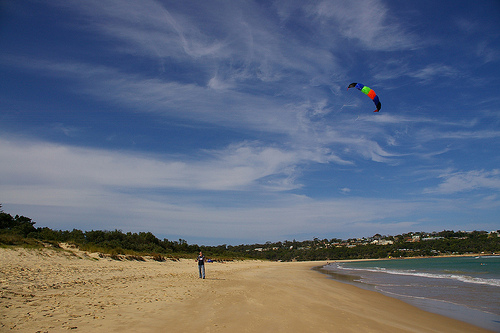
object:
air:
[6, 11, 499, 332]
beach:
[0, 238, 495, 333]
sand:
[0, 235, 499, 333]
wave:
[329, 260, 499, 289]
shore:
[307, 255, 498, 333]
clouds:
[0, 0, 498, 243]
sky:
[1, 2, 500, 247]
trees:
[0, 204, 500, 261]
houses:
[403, 235, 419, 244]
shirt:
[196, 255, 206, 265]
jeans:
[198, 264, 207, 278]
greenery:
[0, 207, 496, 262]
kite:
[342, 81, 382, 114]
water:
[310, 254, 500, 332]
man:
[195, 250, 208, 280]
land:
[0, 238, 496, 332]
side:
[0, 2, 394, 324]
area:
[0, 243, 272, 263]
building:
[364, 238, 392, 245]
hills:
[239, 229, 499, 262]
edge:
[310, 253, 499, 332]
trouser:
[198, 263, 205, 278]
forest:
[0, 204, 499, 262]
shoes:
[202, 277, 205, 280]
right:
[309, 1, 499, 321]